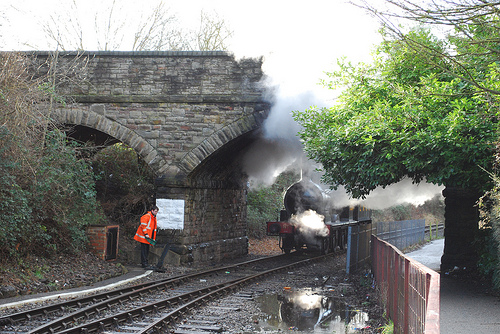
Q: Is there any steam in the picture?
A: Yes, there is steam.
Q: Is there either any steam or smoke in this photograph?
A: Yes, there is steam.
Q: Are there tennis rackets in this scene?
A: No, there are no tennis rackets.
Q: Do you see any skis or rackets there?
A: No, there are no rackets or skis.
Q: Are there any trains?
A: Yes, there is a train.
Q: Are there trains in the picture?
A: Yes, there is a train.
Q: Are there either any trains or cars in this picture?
A: Yes, there is a train.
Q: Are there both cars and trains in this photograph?
A: No, there is a train but no cars.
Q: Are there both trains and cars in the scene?
A: No, there is a train but no cars.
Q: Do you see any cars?
A: No, there are no cars.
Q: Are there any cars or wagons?
A: No, there are no cars or wagons.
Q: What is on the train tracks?
A: The train is on the train tracks.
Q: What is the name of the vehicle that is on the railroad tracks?
A: The vehicle is a train.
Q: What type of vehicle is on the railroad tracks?
A: The vehicle is a train.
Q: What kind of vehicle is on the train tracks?
A: The vehicle is a train.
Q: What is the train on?
A: The train is on the train tracks.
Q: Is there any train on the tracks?
A: Yes, there is a train on the tracks.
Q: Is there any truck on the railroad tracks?
A: No, there is a train on the railroad tracks.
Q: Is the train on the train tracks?
A: Yes, the train is on the train tracks.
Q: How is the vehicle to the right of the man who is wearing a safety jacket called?
A: The vehicle is a train.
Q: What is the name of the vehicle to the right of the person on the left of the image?
A: The vehicle is a train.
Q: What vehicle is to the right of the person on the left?
A: The vehicle is a train.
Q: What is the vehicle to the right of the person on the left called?
A: The vehicle is a train.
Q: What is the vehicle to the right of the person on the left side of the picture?
A: The vehicle is a train.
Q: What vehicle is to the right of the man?
A: The vehicle is a train.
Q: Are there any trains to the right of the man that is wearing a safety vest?
A: Yes, there is a train to the right of the man.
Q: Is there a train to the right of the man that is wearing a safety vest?
A: Yes, there is a train to the right of the man.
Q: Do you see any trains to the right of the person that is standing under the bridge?
A: Yes, there is a train to the right of the man.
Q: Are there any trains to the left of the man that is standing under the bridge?
A: No, the train is to the right of the man.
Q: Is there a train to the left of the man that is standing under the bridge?
A: No, the train is to the right of the man.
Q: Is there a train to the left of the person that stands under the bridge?
A: No, the train is to the right of the man.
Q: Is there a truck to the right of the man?
A: No, there is a train to the right of the man.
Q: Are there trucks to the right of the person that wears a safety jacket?
A: No, there is a train to the right of the man.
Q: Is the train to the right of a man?
A: Yes, the train is to the right of a man.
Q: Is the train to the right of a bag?
A: No, the train is to the right of a man.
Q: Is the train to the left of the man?
A: No, the train is to the right of the man.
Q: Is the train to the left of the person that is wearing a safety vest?
A: No, the train is to the right of the man.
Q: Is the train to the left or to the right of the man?
A: The train is to the right of the man.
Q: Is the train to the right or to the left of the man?
A: The train is to the right of the man.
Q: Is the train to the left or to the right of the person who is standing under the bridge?
A: The train is to the right of the man.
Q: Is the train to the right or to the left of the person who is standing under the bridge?
A: The train is to the right of the man.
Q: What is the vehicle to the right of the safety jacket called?
A: The vehicle is a train.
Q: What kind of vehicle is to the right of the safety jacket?
A: The vehicle is a train.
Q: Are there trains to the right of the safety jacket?
A: Yes, there is a train to the right of the safety jacket.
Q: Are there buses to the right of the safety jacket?
A: No, there is a train to the right of the safety jacket.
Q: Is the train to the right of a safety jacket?
A: Yes, the train is to the right of a safety jacket.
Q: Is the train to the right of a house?
A: No, the train is to the right of a safety jacket.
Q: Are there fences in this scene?
A: Yes, there is a fence.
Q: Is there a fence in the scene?
A: Yes, there is a fence.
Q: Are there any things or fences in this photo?
A: Yes, there is a fence.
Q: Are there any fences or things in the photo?
A: Yes, there is a fence.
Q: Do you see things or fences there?
A: Yes, there is a fence.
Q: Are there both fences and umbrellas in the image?
A: No, there is a fence but no umbrellas.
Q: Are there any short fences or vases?
A: Yes, there is a short fence.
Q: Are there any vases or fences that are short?
A: Yes, the fence is short.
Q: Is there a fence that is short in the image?
A: Yes, there is a short fence.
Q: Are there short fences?
A: Yes, there is a short fence.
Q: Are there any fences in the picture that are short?
A: Yes, there is a fence that is short.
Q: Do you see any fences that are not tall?
A: Yes, there is a short fence.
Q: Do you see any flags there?
A: No, there are no flags.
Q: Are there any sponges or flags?
A: No, there are no flags or sponges.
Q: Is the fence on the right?
A: Yes, the fence is on the right of the image.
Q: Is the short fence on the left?
A: No, the fence is on the right of the image.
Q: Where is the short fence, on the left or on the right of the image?
A: The fence is on the right of the image.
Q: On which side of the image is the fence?
A: The fence is on the right of the image.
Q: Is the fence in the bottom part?
A: Yes, the fence is in the bottom of the image.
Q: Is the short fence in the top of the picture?
A: No, the fence is in the bottom of the image.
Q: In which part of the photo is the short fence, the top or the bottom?
A: The fence is in the bottom of the image.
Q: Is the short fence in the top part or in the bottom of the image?
A: The fence is in the bottom of the image.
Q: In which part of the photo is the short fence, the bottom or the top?
A: The fence is in the bottom of the image.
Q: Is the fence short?
A: Yes, the fence is short.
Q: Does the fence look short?
A: Yes, the fence is short.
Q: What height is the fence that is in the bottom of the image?
A: The fence is short.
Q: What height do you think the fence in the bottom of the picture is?
A: The fence is short.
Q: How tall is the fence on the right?
A: The fence is short.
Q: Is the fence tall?
A: No, the fence is short.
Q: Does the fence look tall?
A: No, the fence is short.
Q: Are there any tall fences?
A: No, there is a fence but it is short.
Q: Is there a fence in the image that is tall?
A: No, there is a fence but it is short.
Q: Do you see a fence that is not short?
A: No, there is a fence but it is short.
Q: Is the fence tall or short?
A: The fence is short.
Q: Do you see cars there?
A: No, there are no cars.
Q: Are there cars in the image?
A: No, there are no cars.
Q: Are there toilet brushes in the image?
A: No, there are no toilet brushes.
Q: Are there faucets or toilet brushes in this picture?
A: No, there are no toilet brushes or faucets.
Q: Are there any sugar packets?
A: No, there are no sugar packets.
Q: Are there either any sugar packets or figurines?
A: No, there are no sugar packets or figurines.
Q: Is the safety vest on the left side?
A: Yes, the safety vest is on the left of the image.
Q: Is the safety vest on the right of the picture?
A: No, the safety vest is on the left of the image.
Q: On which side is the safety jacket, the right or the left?
A: The safety jacket is on the left of the image.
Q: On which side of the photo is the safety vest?
A: The safety vest is on the left of the image.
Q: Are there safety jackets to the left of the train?
A: Yes, there is a safety jacket to the left of the train.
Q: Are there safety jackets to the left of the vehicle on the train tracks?
A: Yes, there is a safety jacket to the left of the train.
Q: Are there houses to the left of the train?
A: No, there is a safety jacket to the left of the train.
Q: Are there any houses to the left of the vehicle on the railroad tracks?
A: No, there is a safety jacket to the left of the train.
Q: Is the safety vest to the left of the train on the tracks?
A: Yes, the safety vest is to the left of the train.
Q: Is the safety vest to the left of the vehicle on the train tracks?
A: Yes, the safety vest is to the left of the train.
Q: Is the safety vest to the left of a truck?
A: No, the safety vest is to the left of the train.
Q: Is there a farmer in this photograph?
A: No, there are no farmers.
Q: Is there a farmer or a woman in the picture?
A: No, there are no farmers or women.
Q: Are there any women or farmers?
A: No, there are no farmers or women.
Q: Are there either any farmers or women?
A: No, there are no farmers or women.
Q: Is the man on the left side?
A: Yes, the man is on the left of the image.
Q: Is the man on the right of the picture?
A: No, the man is on the left of the image.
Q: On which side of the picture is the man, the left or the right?
A: The man is on the left of the image.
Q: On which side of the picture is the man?
A: The man is on the left of the image.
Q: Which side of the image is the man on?
A: The man is on the left of the image.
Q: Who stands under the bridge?
A: The man stands under the bridge.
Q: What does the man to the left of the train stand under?
A: The man stands under the bridge.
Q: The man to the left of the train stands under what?
A: The man stands under the bridge.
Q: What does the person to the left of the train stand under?
A: The man stands under the bridge.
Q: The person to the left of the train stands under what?
A: The man stands under the bridge.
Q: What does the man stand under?
A: The man stands under the bridge.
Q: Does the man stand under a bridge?
A: Yes, the man stands under a bridge.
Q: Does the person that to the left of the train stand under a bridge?
A: Yes, the man stands under a bridge.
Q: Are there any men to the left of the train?
A: Yes, there is a man to the left of the train.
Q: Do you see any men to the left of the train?
A: Yes, there is a man to the left of the train.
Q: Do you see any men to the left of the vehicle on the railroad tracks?
A: Yes, there is a man to the left of the train.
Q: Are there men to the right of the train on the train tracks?
A: No, the man is to the left of the train.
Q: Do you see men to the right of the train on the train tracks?
A: No, the man is to the left of the train.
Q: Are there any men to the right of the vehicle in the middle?
A: No, the man is to the left of the train.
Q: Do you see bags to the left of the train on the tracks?
A: No, there is a man to the left of the train.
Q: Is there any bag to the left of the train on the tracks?
A: No, there is a man to the left of the train.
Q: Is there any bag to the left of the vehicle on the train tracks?
A: No, there is a man to the left of the train.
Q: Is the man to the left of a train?
A: Yes, the man is to the left of a train.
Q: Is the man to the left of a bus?
A: No, the man is to the left of a train.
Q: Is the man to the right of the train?
A: No, the man is to the left of the train.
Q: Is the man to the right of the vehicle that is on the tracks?
A: No, the man is to the left of the train.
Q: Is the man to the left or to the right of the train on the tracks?
A: The man is to the left of the train.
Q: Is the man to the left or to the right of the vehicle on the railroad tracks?
A: The man is to the left of the train.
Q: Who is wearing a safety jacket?
A: The man is wearing a safety jacket.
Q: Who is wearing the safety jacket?
A: The man is wearing a safety jacket.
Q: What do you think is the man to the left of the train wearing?
A: The man is wearing a safety jacket.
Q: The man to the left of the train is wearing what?
A: The man is wearing a safety jacket.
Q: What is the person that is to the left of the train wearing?
A: The man is wearing a safety jacket.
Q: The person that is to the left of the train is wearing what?
A: The man is wearing a safety jacket.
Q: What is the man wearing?
A: The man is wearing a safety jacket.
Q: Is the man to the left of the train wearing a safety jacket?
A: Yes, the man is wearing a safety jacket.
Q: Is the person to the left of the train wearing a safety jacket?
A: Yes, the man is wearing a safety jacket.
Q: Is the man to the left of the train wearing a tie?
A: No, the man is wearing a safety jacket.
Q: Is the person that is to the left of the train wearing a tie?
A: No, the man is wearing a safety jacket.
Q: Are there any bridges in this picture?
A: Yes, there is a bridge.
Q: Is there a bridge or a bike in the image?
A: Yes, there is a bridge.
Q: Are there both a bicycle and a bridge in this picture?
A: No, there is a bridge but no bicycles.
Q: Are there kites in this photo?
A: No, there are no kites.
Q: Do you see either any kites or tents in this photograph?
A: No, there are no kites or tents.